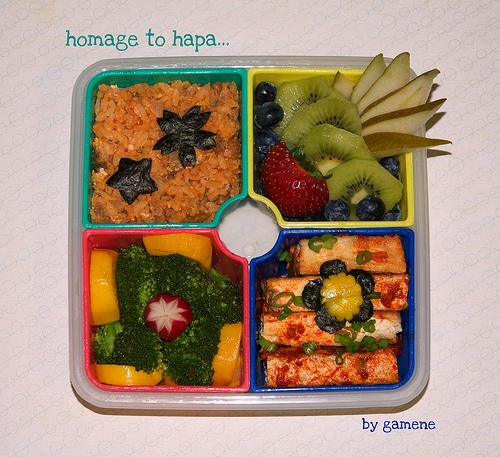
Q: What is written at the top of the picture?
A: Homage to hapa.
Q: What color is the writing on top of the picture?
A: Green.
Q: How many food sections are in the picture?
A: Four.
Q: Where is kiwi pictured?
A: On the top right.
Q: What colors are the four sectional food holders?
A: Green, yellow, red and blue.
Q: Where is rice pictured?
A: On the top left.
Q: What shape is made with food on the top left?
A: Stars.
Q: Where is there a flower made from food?
A: In the bottom right.